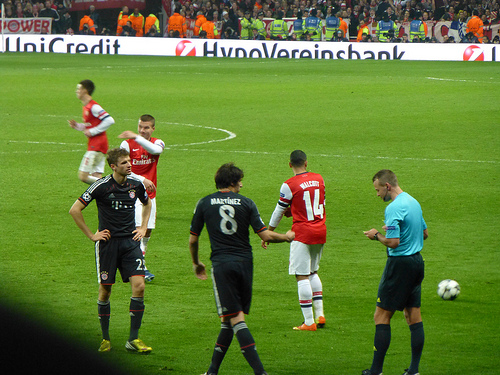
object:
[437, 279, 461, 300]
soccerball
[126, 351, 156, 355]
cleats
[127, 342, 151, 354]
colors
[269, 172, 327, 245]
shirt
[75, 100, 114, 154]
shirt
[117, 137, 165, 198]
shirt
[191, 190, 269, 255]
shirt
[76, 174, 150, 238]
shirt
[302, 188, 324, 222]
number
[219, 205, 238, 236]
number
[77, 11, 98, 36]
people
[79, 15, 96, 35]
jumpsuit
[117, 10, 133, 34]
people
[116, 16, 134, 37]
jumpsuit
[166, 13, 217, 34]
people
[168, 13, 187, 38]
jumpsuit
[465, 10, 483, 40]
people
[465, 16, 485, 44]
jumpsuit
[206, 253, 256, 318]
shorts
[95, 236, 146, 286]
shorts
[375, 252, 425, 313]
shorts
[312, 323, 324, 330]
cleats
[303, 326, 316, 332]
orange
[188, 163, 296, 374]
man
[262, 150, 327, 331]
man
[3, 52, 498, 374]
field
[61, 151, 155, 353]
man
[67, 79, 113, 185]
man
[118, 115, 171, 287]
man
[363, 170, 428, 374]
man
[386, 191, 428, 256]
blue shirt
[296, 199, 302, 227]
red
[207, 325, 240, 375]
long socks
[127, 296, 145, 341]
long socks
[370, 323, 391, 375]
long socks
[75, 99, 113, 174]
red unifrom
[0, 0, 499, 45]
people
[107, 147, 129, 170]
blonde hair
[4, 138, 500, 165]
lines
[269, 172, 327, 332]
uniforms